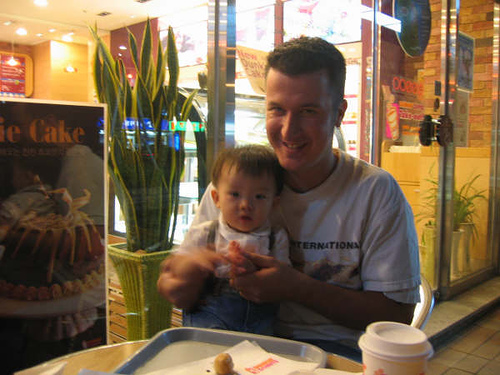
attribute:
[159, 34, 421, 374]
man — sitting, smiling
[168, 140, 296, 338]
baby — surprised, sitting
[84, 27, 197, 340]
plant — green, tall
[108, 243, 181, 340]
pot — green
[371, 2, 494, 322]
frame — silver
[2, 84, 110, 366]
sign — standing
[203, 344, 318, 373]
napkin — white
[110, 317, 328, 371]
tray — gray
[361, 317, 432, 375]
cup — insulated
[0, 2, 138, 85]
light — bright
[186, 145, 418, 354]
shirt — white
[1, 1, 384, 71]
ceiling — bright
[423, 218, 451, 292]
vase — green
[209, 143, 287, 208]
hair — brown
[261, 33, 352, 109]
hair — brown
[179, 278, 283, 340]
jeans — blue